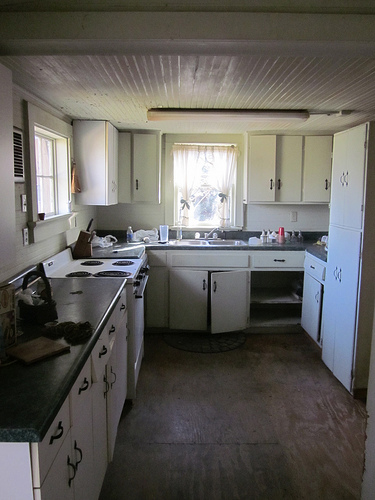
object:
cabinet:
[209, 269, 248, 335]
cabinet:
[168, 266, 209, 332]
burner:
[81, 260, 103, 266]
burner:
[112, 259, 134, 266]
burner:
[65, 270, 90, 278]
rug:
[164, 334, 247, 354]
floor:
[98, 327, 373, 500]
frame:
[159, 135, 241, 230]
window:
[173, 142, 234, 229]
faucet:
[204, 226, 217, 239]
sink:
[208, 239, 243, 247]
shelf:
[252, 289, 303, 304]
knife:
[86, 218, 94, 232]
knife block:
[74, 230, 93, 258]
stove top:
[42, 245, 142, 278]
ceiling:
[7, 51, 375, 134]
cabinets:
[243, 133, 277, 203]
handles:
[269, 178, 273, 189]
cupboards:
[244, 131, 276, 204]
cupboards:
[130, 129, 163, 202]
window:
[34, 127, 60, 219]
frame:
[21, 99, 75, 245]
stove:
[39, 247, 147, 401]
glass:
[160, 224, 169, 242]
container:
[278, 226, 285, 244]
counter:
[66, 236, 327, 262]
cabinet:
[319, 119, 374, 396]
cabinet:
[249, 266, 306, 327]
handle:
[213, 280, 217, 293]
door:
[210, 268, 249, 334]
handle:
[202, 279, 206, 291]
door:
[167, 267, 209, 333]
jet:
[112, 260, 135, 265]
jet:
[81, 259, 105, 265]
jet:
[93, 270, 131, 277]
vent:
[13, 130, 25, 182]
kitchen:
[0, 0, 375, 500]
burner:
[95, 270, 130, 278]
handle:
[134, 280, 141, 287]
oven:
[132, 258, 156, 373]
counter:
[0, 277, 127, 440]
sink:
[175, 240, 209, 247]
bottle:
[126, 226, 133, 243]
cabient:
[49, 421, 65, 450]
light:
[145, 107, 310, 126]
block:
[73, 229, 93, 257]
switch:
[21, 193, 28, 213]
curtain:
[170, 144, 240, 229]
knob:
[139, 273, 146, 281]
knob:
[337, 267, 342, 283]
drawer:
[250, 250, 305, 270]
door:
[300, 273, 322, 345]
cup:
[159, 224, 169, 242]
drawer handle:
[274, 258, 286, 263]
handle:
[67, 455, 77, 488]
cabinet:
[28, 397, 78, 488]